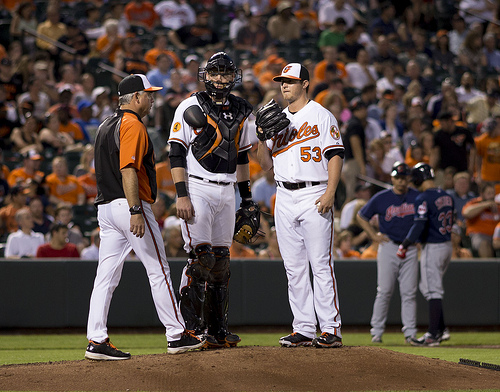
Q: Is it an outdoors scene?
A: Yes, it is outdoors.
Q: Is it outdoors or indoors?
A: It is outdoors.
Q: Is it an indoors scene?
A: No, it is outdoors.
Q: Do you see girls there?
A: No, there are no girls.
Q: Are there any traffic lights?
A: No, there are no traffic lights.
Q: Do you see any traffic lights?
A: No, there are no traffic lights.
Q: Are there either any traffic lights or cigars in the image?
A: No, there are no traffic lights or cigars.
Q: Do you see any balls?
A: No, there are no balls.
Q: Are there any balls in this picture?
A: No, there are no balls.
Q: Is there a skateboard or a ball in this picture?
A: No, there are no balls or skateboards.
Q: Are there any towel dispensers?
A: No, there are no towel dispensers.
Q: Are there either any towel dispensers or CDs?
A: No, there are no towel dispensers or cds.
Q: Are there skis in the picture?
A: No, there are no skis.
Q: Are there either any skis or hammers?
A: No, there are no skis or hammers.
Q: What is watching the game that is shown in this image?
A: The fan is watching the game.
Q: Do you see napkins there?
A: No, there are no napkins.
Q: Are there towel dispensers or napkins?
A: No, there are no napkins or towel dispensers.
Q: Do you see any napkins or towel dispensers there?
A: No, there are no napkins or towel dispensers.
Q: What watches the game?
A: The fan watches the game.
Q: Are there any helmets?
A: Yes, there is a helmet.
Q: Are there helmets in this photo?
A: Yes, there is a helmet.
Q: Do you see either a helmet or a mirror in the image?
A: Yes, there is a helmet.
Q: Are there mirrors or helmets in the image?
A: Yes, there is a helmet.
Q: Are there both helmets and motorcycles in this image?
A: No, there is a helmet but no motorcycles.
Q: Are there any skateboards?
A: No, there are no skateboards.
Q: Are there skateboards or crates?
A: No, there are no skateboards or crates.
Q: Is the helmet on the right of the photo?
A: Yes, the helmet is on the right of the image.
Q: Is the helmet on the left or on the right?
A: The helmet is on the right of the image.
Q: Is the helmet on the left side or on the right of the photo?
A: The helmet is on the right of the image.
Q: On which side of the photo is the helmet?
A: The helmet is on the right of the image.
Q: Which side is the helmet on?
A: The helmet is on the right of the image.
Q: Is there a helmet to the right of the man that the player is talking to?
A: Yes, there is a helmet to the right of the man.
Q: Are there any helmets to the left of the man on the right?
A: No, the helmet is to the right of the man.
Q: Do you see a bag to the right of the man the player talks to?
A: No, there is a helmet to the right of the man.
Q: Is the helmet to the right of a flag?
A: No, the helmet is to the right of a man.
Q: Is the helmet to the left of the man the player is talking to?
A: No, the helmet is to the right of the man.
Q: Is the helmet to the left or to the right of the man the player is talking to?
A: The helmet is to the right of the man.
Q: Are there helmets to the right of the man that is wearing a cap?
A: Yes, there is a helmet to the right of the man.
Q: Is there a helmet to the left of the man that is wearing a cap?
A: No, the helmet is to the right of the man.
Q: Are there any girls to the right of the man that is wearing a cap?
A: No, there is a helmet to the right of the man.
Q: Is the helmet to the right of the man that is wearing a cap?
A: Yes, the helmet is to the right of the man.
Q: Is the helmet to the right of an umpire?
A: No, the helmet is to the right of the man.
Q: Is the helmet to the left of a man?
A: No, the helmet is to the right of a man.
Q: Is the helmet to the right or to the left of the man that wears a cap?
A: The helmet is to the right of the man.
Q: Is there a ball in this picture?
A: No, there are no balls.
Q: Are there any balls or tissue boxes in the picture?
A: No, there are no balls or tissue boxes.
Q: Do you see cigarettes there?
A: No, there are no cigarettes.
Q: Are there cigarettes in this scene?
A: No, there are no cigarettes.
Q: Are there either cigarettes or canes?
A: No, there are no cigarettes or canes.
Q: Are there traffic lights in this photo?
A: No, there are no traffic lights.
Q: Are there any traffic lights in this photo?
A: No, there are no traffic lights.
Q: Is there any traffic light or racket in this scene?
A: No, there are no traffic lights or rackets.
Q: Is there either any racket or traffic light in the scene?
A: No, there are no traffic lights or rackets.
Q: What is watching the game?
A: The fan is watching the game.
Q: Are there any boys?
A: No, there are no boys.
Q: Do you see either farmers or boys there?
A: No, there are no boys or farmers.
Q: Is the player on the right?
A: Yes, the player is on the right of the image.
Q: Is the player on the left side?
A: No, the player is on the right of the image.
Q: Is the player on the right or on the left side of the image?
A: The player is on the right of the image.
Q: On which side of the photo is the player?
A: The player is on the right of the image.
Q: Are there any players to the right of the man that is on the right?
A: Yes, there is a player to the right of the man.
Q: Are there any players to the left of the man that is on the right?
A: No, the player is to the right of the man.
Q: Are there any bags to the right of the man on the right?
A: No, there is a player to the right of the man.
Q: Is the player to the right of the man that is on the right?
A: Yes, the player is to the right of the man.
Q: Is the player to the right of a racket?
A: No, the player is to the right of the man.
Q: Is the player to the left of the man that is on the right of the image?
A: No, the player is to the right of the man.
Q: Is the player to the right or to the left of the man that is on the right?
A: The player is to the right of the man.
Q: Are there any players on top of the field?
A: Yes, there is a player on top of the field.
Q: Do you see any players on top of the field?
A: Yes, there is a player on top of the field.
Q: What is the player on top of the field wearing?
A: The player is wearing a uniform.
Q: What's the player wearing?
A: The player is wearing a uniform.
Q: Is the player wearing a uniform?
A: Yes, the player is wearing a uniform.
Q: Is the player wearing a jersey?
A: No, the player is wearing a uniform.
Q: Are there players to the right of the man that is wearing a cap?
A: Yes, there is a player to the right of the man.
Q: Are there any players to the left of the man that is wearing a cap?
A: No, the player is to the right of the man.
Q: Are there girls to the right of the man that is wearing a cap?
A: No, there is a player to the right of the man.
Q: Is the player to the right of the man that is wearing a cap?
A: Yes, the player is to the right of the man.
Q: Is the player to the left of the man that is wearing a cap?
A: No, the player is to the right of the man.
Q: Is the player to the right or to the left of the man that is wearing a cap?
A: The player is to the right of the man.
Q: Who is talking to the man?
A: The player is talking to the man.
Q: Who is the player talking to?
A: The player is talking to a man.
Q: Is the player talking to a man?
A: Yes, the player is talking to a man.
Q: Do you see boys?
A: No, there are no boys.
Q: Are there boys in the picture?
A: No, there are no boys.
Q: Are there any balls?
A: No, there are no balls.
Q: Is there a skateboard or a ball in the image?
A: No, there are no balls or skateboards.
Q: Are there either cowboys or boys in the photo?
A: No, there are no boys or cowboys.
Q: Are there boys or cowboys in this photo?
A: No, there are no boys or cowboys.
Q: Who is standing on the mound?
A: The man is standing on the mound.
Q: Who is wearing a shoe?
A: The man is wearing a shoe.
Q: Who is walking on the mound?
A: The man is walking on the mound.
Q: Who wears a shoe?
A: The man wears a shoe.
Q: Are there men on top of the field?
A: Yes, there is a man on top of the field.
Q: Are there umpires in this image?
A: No, there are no umpires.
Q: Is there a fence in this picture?
A: Yes, there is a fence.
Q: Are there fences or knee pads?
A: Yes, there is a fence.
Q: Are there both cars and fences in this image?
A: No, there is a fence but no cars.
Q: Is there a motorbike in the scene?
A: No, there are no motorcycles.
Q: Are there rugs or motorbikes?
A: No, there are no motorbikes or rugs.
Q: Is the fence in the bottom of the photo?
A: Yes, the fence is in the bottom of the image.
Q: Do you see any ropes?
A: No, there are no ropes.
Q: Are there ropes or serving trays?
A: No, there are no ropes or serving trays.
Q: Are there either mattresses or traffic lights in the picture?
A: No, there are no traffic lights or mattresses.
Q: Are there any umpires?
A: No, there are no umpires.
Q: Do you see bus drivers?
A: No, there are no bus drivers.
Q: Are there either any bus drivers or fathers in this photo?
A: No, there are no bus drivers or fathers.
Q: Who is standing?
A: The man is standing.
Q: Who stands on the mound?
A: The man stands on the mound.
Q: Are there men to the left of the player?
A: Yes, there is a man to the left of the player.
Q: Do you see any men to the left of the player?
A: Yes, there is a man to the left of the player.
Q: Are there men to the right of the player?
A: No, the man is to the left of the player.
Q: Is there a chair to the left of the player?
A: No, there is a man to the left of the player.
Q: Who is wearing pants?
A: The man is wearing pants.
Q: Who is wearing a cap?
A: The man is wearing a cap.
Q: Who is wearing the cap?
A: The man is wearing a cap.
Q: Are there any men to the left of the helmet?
A: Yes, there is a man to the left of the helmet.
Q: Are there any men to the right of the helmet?
A: No, the man is to the left of the helmet.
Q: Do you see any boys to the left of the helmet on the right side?
A: No, there is a man to the left of the helmet.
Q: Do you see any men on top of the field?
A: Yes, there is a man on top of the field.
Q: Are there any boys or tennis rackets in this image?
A: No, there are no boys or tennis rackets.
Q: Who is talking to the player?
A: The man is talking to the player.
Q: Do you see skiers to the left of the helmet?
A: No, there is a man to the left of the helmet.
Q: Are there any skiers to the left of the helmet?
A: No, there is a man to the left of the helmet.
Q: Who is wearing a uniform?
A: The man is wearing a uniform.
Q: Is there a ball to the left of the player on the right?
A: No, there is a man to the left of the player.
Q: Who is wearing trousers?
A: The man is wearing trousers.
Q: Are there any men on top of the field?
A: Yes, there is a man on top of the field.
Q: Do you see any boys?
A: No, there are no boys.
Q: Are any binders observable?
A: No, there are no binders.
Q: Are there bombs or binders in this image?
A: No, there are no binders or bombs.